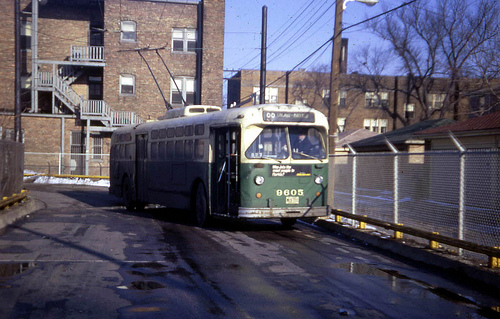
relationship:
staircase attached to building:
[33, 63, 133, 133] [2, 1, 224, 108]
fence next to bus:
[326, 133, 496, 252] [87, 40, 342, 234]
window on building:
[120, 20, 138, 41] [4, 0, 224, 177]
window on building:
[171, 25, 201, 52] [4, 0, 224, 177]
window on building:
[119, 73, 136, 96] [4, 0, 224, 177]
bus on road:
[115, 127, 322, 234] [45, 220, 442, 300]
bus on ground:
[109, 104, 330, 226] [0, 183, 499, 319]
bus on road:
[109, 104, 330, 226] [0, 183, 498, 315]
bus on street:
[109, 104, 330, 226] [27, 203, 443, 295]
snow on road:
[43, 162, 85, 192] [24, 166, 115, 192]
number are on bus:
[274, 186, 306, 197] [109, 104, 330, 226]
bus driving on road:
[109, 104, 330, 226] [0, 183, 498, 315]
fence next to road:
[326, 147, 500, 258] [7, 181, 463, 314]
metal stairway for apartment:
[17, 41, 141, 136] [0, 1, 224, 182]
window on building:
[115, 70, 136, 97] [4, 0, 224, 177]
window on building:
[165, 73, 195, 104] [4, 0, 224, 177]